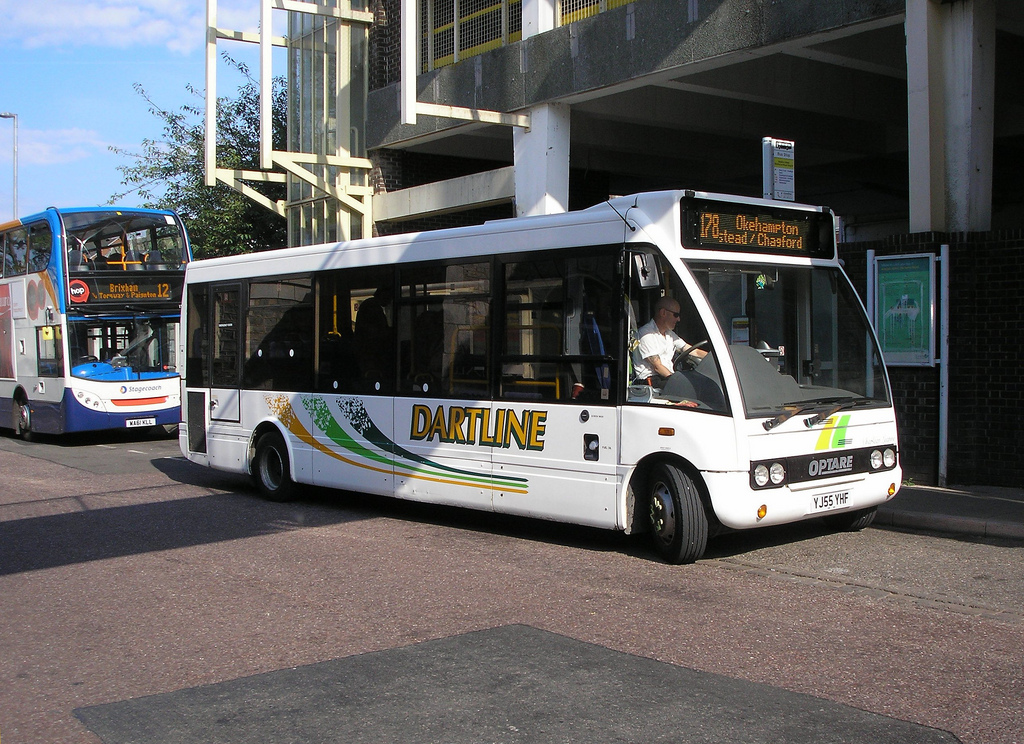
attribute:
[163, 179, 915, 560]
bus — white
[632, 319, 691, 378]
shirt — white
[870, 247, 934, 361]
sign — green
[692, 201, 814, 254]
lights — digital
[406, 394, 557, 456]
dartline writing — gold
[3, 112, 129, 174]
clouds — white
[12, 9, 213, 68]
clouds — white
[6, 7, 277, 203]
sky — blue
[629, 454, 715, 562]
tire — black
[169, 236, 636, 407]
window — tinted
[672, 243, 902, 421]
window — glass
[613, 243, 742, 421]
window — glass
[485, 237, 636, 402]
window — glass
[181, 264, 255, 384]
window — glass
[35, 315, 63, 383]
window — glass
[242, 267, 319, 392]
window — glass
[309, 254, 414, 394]
window — glass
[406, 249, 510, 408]
window — glass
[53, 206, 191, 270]
window — glass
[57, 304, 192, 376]
window — glass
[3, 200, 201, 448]
bus — blue, white, double level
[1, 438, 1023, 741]
street — gray